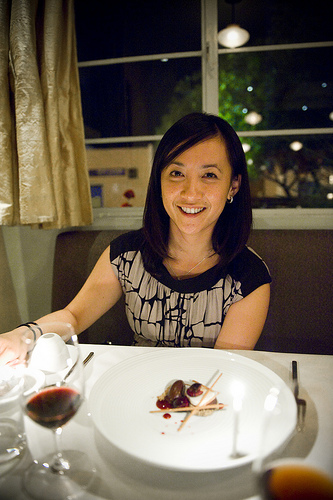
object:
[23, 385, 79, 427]
wine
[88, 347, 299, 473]
plate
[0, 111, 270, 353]
woman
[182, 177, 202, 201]
nose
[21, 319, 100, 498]
glass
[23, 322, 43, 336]
bracelet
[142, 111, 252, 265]
hair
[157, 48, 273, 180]
tree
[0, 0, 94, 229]
curtain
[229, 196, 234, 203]
earring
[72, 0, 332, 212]
window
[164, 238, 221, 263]
necklace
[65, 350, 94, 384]
chopstick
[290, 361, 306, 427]
fork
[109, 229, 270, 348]
blouse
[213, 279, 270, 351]
arm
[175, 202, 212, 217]
smile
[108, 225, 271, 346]
top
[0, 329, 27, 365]
hand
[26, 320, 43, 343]
band